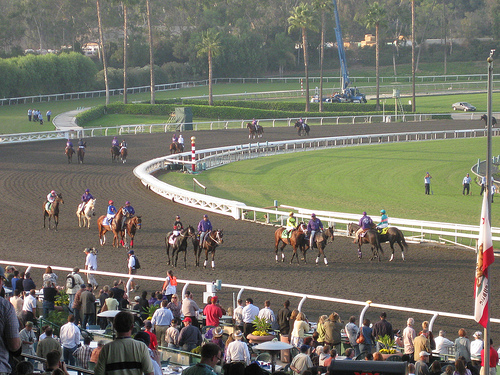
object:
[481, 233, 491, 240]
white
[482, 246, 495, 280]
red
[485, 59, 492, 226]
pole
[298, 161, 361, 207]
grassy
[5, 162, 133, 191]
track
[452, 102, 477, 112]
car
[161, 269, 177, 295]
woman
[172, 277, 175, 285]
orange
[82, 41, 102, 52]
house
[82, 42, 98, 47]
roof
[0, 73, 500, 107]
fence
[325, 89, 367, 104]
truck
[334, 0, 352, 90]
ladder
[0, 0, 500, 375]
background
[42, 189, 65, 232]
jockey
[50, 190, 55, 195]
helmet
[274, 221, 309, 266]
horse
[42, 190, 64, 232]
horses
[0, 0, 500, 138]
outside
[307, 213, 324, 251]
people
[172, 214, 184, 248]
person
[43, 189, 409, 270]
race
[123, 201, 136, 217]
person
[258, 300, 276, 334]
man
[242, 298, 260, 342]
man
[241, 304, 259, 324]
shirt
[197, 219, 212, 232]
shirt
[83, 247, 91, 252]
hat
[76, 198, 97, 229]
horse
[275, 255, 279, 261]
bandanges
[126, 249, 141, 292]
man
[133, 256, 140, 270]
backpack